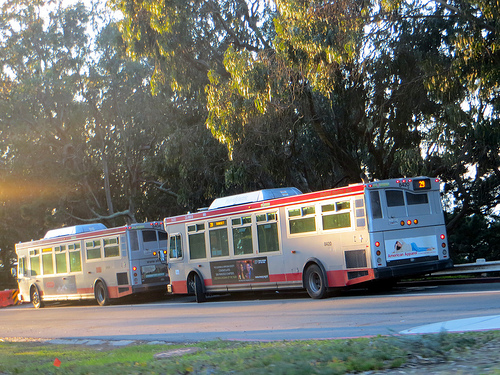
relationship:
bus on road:
[12, 216, 177, 308] [0, 289, 498, 333]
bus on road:
[159, 172, 460, 302] [0, 289, 498, 333]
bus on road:
[12, 216, 177, 308] [0, 289, 498, 342]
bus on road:
[159, 172, 460, 302] [0, 289, 498, 342]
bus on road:
[12, 216, 177, 308] [1, 274, 498, 347]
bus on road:
[159, 172, 460, 302] [1, 274, 498, 347]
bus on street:
[159, 172, 460, 302] [4, 269, 494, 342]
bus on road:
[159, 172, 460, 302] [1, 264, 496, 349]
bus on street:
[9, 216, 164, 307] [3, 279, 497, 345]